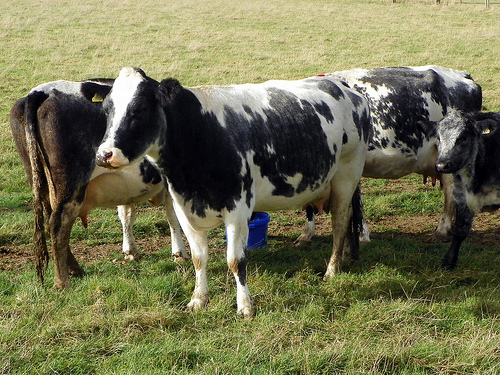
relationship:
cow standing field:
[434, 100, 498, 268] [10, 319, 497, 373]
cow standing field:
[291, 64, 482, 270] [7, 8, 478, 77]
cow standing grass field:
[9, 78, 191, 290] [254, 9, 342, 54]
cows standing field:
[80, 66, 369, 320] [250, 296, 454, 374]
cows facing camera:
[80, 66, 369, 320] [5, 54, 484, 374]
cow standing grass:
[9, 78, 191, 290] [3, 0, 494, 373]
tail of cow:
[24, 89, 48, 287] [9, 78, 191, 290]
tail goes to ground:
[24, 89, 48, 287] [4, 2, 497, 373]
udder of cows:
[310, 183, 331, 214] [80, 66, 369, 320]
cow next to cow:
[9, 78, 191, 290] [109, 40, 402, 326]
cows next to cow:
[80, 66, 369, 320] [9, 78, 191, 290]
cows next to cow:
[80, 66, 369, 320] [289, 61, 487, 271]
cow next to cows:
[434, 100, 498, 268] [80, 66, 369, 320]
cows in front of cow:
[80, 66, 369, 320] [315, 64, 482, 264]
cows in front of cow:
[80, 66, 369, 320] [416, 112, 500, 270]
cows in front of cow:
[80, 66, 369, 320] [9, 78, 191, 290]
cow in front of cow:
[416, 112, 500, 270] [245, 66, 482, 259]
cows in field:
[80, 66, 369, 320] [20, 7, 465, 59]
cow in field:
[9, 78, 191, 290] [20, 7, 465, 59]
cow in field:
[302, 64, 482, 274] [20, 7, 465, 59]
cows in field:
[80, 66, 369, 320] [2, 0, 497, 373]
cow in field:
[291, 64, 482, 270] [2, 0, 497, 373]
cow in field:
[9, 81, 185, 295] [2, 0, 497, 373]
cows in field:
[126, 46, 412, 331] [2, 0, 497, 373]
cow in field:
[9, 78, 191, 290] [2, 0, 497, 373]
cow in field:
[434, 100, 498, 268] [2, 0, 497, 373]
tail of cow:
[22, 86, 53, 283] [91, 14, 382, 318]